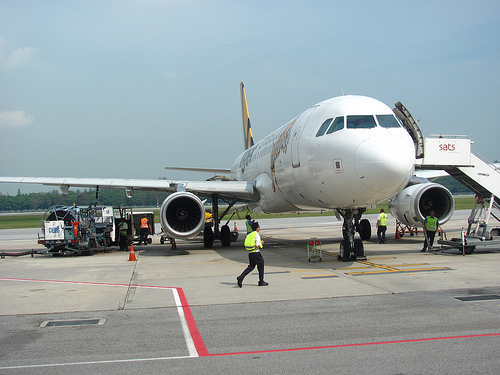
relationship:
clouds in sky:
[4, 34, 277, 74] [2, 1, 498, 200]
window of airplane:
[341, 110, 379, 132] [0, 93, 500, 254]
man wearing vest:
[228, 208, 284, 294] [243, 230, 263, 254]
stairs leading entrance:
[418, 135, 498, 195] [394, 101, 427, 159]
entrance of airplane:
[394, 101, 427, 159] [0, 93, 500, 254]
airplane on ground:
[0, 93, 499, 269] [5, 227, 484, 363]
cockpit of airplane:
[319, 111, 407, 135] [140, 92, 451, 227]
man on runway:
[228, 208, 270, 294] [225, 210, 268, 299]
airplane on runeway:
[0, 93, 500, 254] [8, 246, 493, 361]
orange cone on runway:
[86, 245, 150, 278] [0, 217, 500, 374]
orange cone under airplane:
[123, 245, 151, 263] [0, 93, 500, 254]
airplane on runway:
[0, 93, 500, 254] [0, 217, 500, 374]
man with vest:
[228, 208, 270, 294] [241, 231, 262, 259]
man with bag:
[228, 208, 270, 294] [241, 230, 262, 250]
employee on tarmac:
[415, 211, 438, 253] [363, 236, 498, 326]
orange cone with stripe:
[123, 245, 151, 263] [119, 248, 136, 258]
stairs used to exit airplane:
[440, 135, 497, 195] [0, 93, 499, 269]